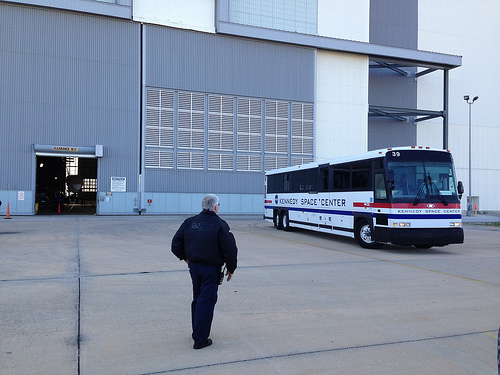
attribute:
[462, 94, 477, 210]
pole — tall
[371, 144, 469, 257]
bus — red, white, blue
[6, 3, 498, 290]
building — gray , white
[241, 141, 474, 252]
white bus — large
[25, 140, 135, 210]
door — garage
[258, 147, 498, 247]
bus — Red , white, blue 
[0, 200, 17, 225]
cone — orange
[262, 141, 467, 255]
bus — tour, white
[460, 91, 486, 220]
street lamo — off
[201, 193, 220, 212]
hair — gray